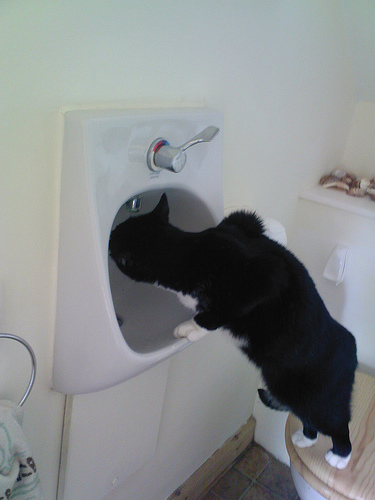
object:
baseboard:
[166, 416, 295, 498]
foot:
[290, 426, 318, 449]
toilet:
[284, 371, 372, 497]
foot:
[174, 320, 197, 337]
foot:
[189, 327, 204, 342]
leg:
[189, 286, 252, 338]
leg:
[318, 372, 351, 458]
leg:
[297, 418, 317, 440]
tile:
[181, 415, 311, 500]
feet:
[321, 446, 351, 471]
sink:
[49, 100, 233, 399]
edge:
[264, 220, 286, 240]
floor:
[171, 412, 316, 498]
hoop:
[0, 323, 38, 404]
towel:
[0, 406, 26, 500]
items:
[319, 167, 374, 199]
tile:
[211, 466, 254, 497]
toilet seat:
[280, 364, 373, 500]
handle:
[145, 122, 217, 175]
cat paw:
[291, 431, 312, 451]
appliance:
[50, 110, 226, 397]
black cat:
[109, 191, 358, 470]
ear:
[150, 192, 170, 229]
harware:
[145, 135, 165, 173]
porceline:
[50, 109, 223, 396]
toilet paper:
[259, 216, 288, 247]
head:
[107, 189, 191, 290]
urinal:
[51, 108, 226, 394]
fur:
[210, 258, 267, 293]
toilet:
[251, 165, 374, 500]